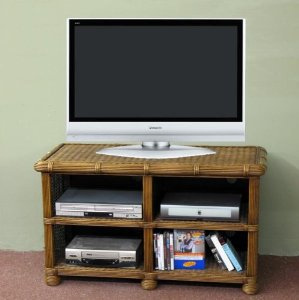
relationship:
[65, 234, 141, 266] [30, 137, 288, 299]
drawer of table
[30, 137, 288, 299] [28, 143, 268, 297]
table of television stand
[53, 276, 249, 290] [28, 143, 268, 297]
underneath of television stand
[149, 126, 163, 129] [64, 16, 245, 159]
logo on tv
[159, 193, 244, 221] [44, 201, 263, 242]
dvd player on shelf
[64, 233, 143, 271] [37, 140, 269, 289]
vhs player in entertainment unit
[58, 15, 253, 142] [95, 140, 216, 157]
tv on stand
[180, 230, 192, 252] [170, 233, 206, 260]
man on book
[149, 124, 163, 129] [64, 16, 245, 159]
logo on tv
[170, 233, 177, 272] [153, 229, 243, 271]
dvd in a collection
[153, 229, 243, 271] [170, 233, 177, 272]
collection of dvd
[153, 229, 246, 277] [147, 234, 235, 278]
books in a collection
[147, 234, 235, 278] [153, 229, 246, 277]
collection of books